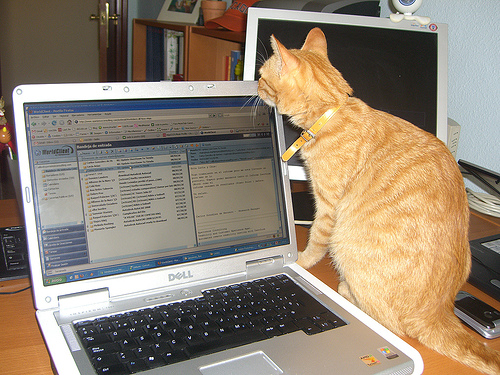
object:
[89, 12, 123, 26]
handle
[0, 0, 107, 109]
door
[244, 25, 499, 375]
cat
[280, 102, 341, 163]
collar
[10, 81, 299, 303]
lid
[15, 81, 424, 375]
laptop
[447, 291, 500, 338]
phone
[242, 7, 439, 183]
monitor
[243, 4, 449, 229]
computer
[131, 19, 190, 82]
shelves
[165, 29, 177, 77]
books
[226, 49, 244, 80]
book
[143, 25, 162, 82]
book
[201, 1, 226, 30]
pot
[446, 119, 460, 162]
modem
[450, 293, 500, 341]
cellphone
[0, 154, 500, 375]
table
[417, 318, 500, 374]
tail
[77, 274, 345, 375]
keyboard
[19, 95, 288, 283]
screen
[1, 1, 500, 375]
room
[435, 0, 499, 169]
wall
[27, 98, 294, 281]
software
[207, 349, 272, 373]
pad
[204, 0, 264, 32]
cap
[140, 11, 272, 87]
shelf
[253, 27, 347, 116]
head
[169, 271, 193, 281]
writing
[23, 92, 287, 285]
monitor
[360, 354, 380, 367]
sticker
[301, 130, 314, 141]
buckle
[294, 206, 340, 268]
leg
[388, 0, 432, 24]
camera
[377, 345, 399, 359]
logo